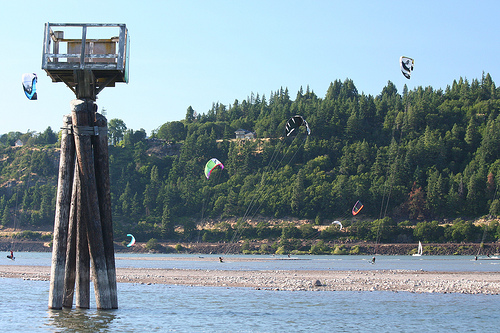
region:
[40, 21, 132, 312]
a tower on the beach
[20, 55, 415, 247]
kites flying in the air over the beach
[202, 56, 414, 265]
people kite surfboarding on the beach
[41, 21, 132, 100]
the top of the tower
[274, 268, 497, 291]
sand and rocks between the bodies of the water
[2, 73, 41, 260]
a person surfboarding with a blue and black kite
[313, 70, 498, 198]
green trees on a hill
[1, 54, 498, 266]
people kite surfboarding at the beach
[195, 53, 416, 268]
surfers on the beach kite surfboarding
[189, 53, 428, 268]
young people kite surfing on a warm summer day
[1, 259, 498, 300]
piece of land in the water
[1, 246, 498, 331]
body of water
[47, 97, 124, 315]
posts standing in the water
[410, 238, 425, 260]
white sailboat in the water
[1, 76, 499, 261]
hill side full of trees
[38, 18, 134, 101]
stand built upon some posts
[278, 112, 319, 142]
black colored parasail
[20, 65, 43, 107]
blue and black parasail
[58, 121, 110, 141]
brace holding poles together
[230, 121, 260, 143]
house on the hill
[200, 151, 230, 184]
a green and pink kite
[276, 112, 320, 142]
a black and white kite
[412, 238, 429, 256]
a white sail on the boat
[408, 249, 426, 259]
a white boat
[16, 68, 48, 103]
a white, black, and blue kite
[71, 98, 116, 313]
a large brown log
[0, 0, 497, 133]
a clear blue sky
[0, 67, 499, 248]
green trees on the mountain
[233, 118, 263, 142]
a building on the mountain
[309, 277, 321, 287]
a rock on the ground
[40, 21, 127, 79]
a platform for observing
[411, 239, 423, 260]
a windsurfing person on the water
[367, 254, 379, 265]
person parasailing on the water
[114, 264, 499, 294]
a rocky sandbar in the water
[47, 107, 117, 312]
support poles for the platform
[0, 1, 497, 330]
a scene on a river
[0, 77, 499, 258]
a hill across the river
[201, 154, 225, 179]
parasail in the air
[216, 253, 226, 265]
a person on the water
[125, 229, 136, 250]
a low flying parasail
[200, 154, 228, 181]
a green and pink water kite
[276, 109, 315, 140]
a black and white water kite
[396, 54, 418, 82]
a white and black water kite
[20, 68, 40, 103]
a white and blue water kite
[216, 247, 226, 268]
a person holding a water kite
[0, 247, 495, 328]
people in the water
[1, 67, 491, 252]
trees in the distance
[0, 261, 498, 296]
a patch of ground between the water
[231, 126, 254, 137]
a white and blue house in the distance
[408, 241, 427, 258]
a white boat in the distance